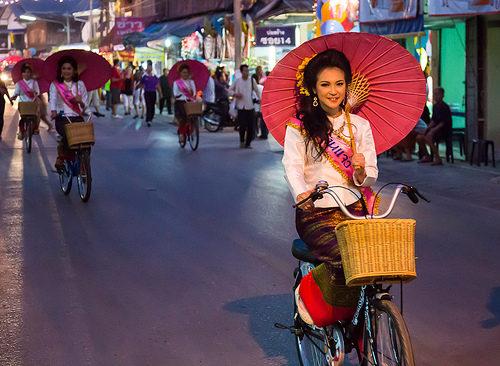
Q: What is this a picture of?
A: Girls with red umbrellas riding bicycles in a parade.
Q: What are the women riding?
A: Bicycles.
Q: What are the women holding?
A: Umbrellas.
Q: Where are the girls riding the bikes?
A: In the street.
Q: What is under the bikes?
A: The street.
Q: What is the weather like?
A: Not raining.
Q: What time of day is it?
A: Twilight.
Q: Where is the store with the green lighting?
A: Behind the woman in front.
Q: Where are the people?
A: Walking in the street.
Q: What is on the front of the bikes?
A: Basket.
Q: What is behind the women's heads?
A: Umbrella.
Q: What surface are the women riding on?
A: Street.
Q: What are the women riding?
A: Bikes.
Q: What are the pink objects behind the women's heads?
A: Umbrellas.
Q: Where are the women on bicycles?
A: In the street.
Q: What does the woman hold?
A: An umbrella.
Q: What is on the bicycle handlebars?
A: A basket.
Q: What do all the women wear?
A: Sashes.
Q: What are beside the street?
A: Shops.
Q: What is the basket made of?
A: Wicker.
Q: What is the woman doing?
A: Riding the bicycle.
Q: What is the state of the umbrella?
A: Open.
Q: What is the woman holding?
A: An umbrella.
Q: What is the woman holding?
A: Pink umbrella.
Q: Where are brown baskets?
A: Front of the bikes.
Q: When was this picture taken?
A: Night time.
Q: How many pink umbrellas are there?
A: Four.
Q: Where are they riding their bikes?
A: In the street.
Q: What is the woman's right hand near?
A: Bell.